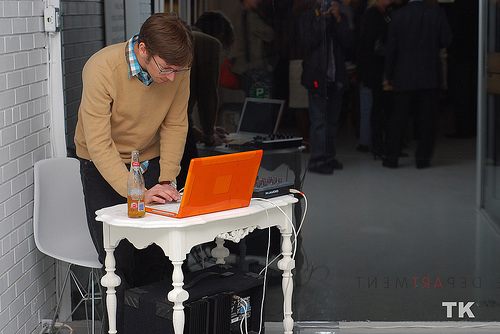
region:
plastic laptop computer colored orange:
[132, 144, 270, 221]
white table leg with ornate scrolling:
[97, 236, 128, 333]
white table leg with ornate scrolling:
[164, 247, 190, 332]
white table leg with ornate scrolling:
[273, 230, 300, 332]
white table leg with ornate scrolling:
[210, 237, 231, 265]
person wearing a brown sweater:
[72, 12, 208, 209]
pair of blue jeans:
[300, 66, 353, 170]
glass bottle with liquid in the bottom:
[122, 146, 149, 221]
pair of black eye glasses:
[150, 51, 197, 79]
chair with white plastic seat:
[22, 150, 117, 332]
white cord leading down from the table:
[235, 199, 276, 332]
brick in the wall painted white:
[15, 148, 35, 175]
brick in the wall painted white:
[7, 170, 29, 195]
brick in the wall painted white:
[26, 77, 45, 100]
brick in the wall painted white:
[11, 82, 33, 105]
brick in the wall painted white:
[12, 116, 34, 141]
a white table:
[99, 182, 304, 332]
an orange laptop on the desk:
[151, 150, 262, 210]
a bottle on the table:
[125, 146, 148, 214]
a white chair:
[26, 147, 133, 327]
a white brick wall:
[2, 5, 64, 320]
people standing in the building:
[303, 0, 457, 153]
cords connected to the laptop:
[251, 197, 306, 315]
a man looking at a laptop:
[85, 27, 266, 220]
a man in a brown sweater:
[88, 15, 190, 197]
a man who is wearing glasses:
[79, 14, 209, 209]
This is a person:
[68, 7, 197, 330]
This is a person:
[186, 7, 260, 221]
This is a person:
[282, 2, 367, 199]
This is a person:
[370, 10, 445, 204]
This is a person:
[348, 21, 383, 199]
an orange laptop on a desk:
[143, 150, 261, 216]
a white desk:
[94, 202, 297, 332]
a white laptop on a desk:
[228, 96, 283, 143]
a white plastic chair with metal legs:
[33, 156, 104, 332]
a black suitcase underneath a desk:
[123, 260, 263, 332]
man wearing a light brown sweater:
[75, 35, 191, 197]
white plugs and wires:
[233, 187, 308, 332]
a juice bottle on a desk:
[126, 149, 144, 217]